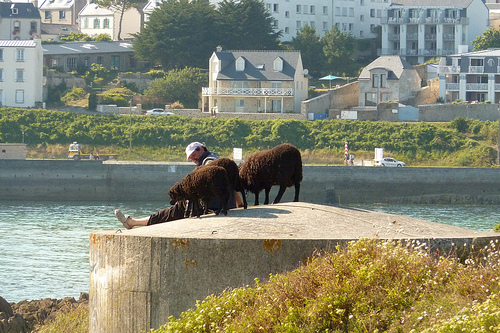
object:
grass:
[40, 236, 499, 332]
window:
[379, 92, 394, 102]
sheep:
[236, 141, 303, 207]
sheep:
[165, 164, 234, 220]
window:
[100, 16, 107, 29]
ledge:
[90, 200, 499, 332]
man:
[114, 141, 239, 230]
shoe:
[114, 208, 140, 233]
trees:
[212, 0, 282, 46]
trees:
[131, 0, 226, 68]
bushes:
[0, 108, 447, 151]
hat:
[185, 142, 205, 159]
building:
[269, 0, 489, 67]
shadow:
[201, 204, 293, 221]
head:
[184, 142, 206, 165]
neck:
[173, 181, 186, 196]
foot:
[114, 209, 139, 233]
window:
[267, 79, 287, 94]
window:
[235, 59, 244, 71]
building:
[200, 44, 312, 119]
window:
[293, 3, 301, 13]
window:
[305, 3, 315, 16]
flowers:
[473, 238, 500, 274]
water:
[0, 197, 499, 303]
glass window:
[370, 75, 383, 89]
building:
[341, 55, 421, 120]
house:
[199, 45, 310, 119]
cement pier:
[85, 197, 499, 331]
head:
[164, 181, 185, 205]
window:
[295, 2, 302, 16]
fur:
[177, 168, 237, 210]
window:
[383, 72, 396, 97]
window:
[237, 82, 242, 89]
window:
[363, 90, 378, 106]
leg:
[183, 196, 193, 221]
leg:
[192, 195, 197, 219]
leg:
[250, 186, 260, 206]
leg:
[260, 183, 271, 205]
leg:
[213, 200, 221, 216]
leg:
[220, 184, 230, 215]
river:
[0, 198, 500, 304]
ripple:
[48, 246, 90, 255]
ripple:
[47, 266, 90, 273]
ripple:
[2, 280, 22, 286]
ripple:
[3, 249, 37, 258]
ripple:
[2, 208, 46, 214]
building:
[34, 1, 85, 34]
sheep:
[193, 156, 250, 211]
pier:
[0, 157, 500, 205]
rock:
[77, 290, 89, 300]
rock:
[57, 295, 77, 305]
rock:
[15, 300, 27, 313]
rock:
[5, 309, 27, 330]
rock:
[0, 294, 13, 315]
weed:
[417, 294, 485, 329]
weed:
[346, 297, 378, 329]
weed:
[352, 259, 383, 293]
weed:
[168, 310, 180, 330]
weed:
[251, 273, 260, 289]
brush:
[453, 265, 484, 305]